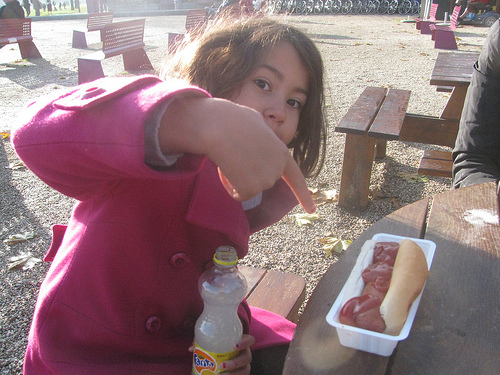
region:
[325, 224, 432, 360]
a hotdog with ketchup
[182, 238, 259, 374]
a bottle of Fanta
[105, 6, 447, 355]
a girl pointing at a hotdog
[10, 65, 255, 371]
a pink pea coat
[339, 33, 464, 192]
a wooden picnic table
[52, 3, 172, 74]
red park benches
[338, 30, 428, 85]
ground covered in gravel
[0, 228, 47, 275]
leaves lying on the gravel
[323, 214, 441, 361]
a hotdog in a white container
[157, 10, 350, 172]
a girl with brown hair and eyes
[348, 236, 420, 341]
A hot dog with ketchup.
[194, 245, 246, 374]
A bottle of fanta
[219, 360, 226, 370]
A pink painted fingernail.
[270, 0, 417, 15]
A row of bicycles.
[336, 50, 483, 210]
A wooden park bench.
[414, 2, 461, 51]
A pair of benches.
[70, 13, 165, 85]
Pink benchs at the park.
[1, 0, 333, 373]
A girl sitting down.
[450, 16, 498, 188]
The arm on a person.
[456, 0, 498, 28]
A person sits in on a scooter cart.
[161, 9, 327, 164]
the head of a girl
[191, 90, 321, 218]
the hand of a girl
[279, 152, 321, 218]
the finger of a girl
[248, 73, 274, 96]
the eye of a girl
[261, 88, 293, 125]
the nose of a girl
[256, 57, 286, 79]
the eyebrow of a girl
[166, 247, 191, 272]
a pink button on the coat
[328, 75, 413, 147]
the brown seat of a bench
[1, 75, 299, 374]
a pink coat on the girl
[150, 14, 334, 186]
the brown hair of the girl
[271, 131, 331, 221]
Girl points finger at hotdog.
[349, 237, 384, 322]
Hotdog with ketchup.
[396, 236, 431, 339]
Warm toasted hotdog bun.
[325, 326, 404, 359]
White bowl on round table.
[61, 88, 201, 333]
Girl wears pink coat.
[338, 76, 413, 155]
Brown bench for people to sit.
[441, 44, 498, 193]
Person wears black jacket.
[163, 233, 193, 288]
Pink button on pink coat.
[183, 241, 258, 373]
Lemonade in girls hand.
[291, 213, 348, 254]
Green leaves on the ground.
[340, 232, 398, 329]
a ton of ketchup on a hot dog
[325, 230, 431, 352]
a white plastic hot dog container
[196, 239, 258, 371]
a plastic fanta bottle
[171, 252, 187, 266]
a pink plastic button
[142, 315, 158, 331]
a pink plastic button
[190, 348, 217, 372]
a orange and blue fanta label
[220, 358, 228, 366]
a pink finger nail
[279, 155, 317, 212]
a pointer finger pointing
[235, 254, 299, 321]
a dark wooden bench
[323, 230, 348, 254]
a yellow leaf